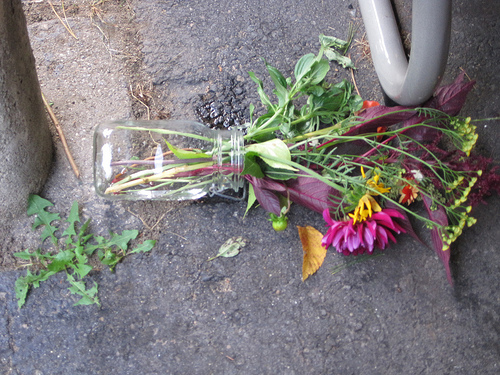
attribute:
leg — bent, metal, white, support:
[359, 0, 462, 107]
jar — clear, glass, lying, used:
[87, 110, 250, 211]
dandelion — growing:
[7, 188, 149, 318]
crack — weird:
[5, 193, 182, 291]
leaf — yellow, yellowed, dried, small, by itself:
[296, 221, 333, 278]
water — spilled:
[189, 74, 260, 133]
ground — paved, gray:
[4, 8, 498, 365]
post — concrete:
[5, 0, 59, 212]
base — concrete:
[7, 1, 68, 211]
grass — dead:
[124, 31, 186, 223]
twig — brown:
[45, 95, 85, 189]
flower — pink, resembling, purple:
[319, 202, 411, 257]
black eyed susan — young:
[348, 170, 392, 220]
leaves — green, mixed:
[241, 28, 374, 210]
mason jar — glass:
[90, 113, 247, 210]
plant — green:
[12, 189, 160, 310]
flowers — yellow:
[333, 165, 395, 220]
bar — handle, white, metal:
[356, 3, 454, 119]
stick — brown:
[42, 87, 95, 195]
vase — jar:
[92, 108, 245, 203]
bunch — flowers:
[246, 30, 491, 258]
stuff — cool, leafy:
[211, 218, 327, 276]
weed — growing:
[14, 187, 156, 314]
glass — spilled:
[92, 108, 252, 207]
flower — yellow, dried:
[353, 170, 389, 225]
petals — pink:
[312, 202, 410, 253]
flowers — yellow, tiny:
[419, 111, 491, 250]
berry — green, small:
[270, 216, 290, 231]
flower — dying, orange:
[391, 173, 423, 204]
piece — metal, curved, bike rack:
[360, 0, 465, 107]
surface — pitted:
[2, 4, 497, 368]